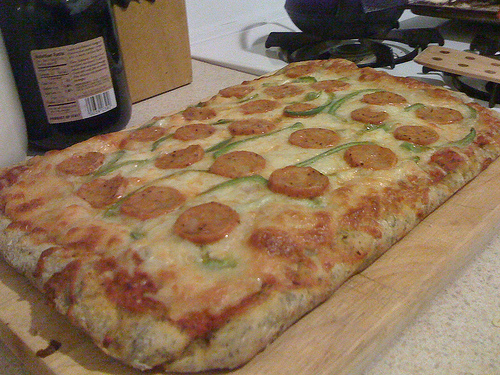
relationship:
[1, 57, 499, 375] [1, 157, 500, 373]
pizza on a board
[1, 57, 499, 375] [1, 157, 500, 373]
pizza on top of a board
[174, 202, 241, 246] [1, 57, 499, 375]
pepperoni on top of pizza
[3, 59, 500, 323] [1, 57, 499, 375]
cheese on top of pizza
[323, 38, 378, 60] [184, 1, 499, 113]
fire on stovetop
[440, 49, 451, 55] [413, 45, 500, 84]
hole in a spatula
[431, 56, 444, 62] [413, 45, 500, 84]
hole in a spatula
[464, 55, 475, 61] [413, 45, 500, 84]
hole in a spatula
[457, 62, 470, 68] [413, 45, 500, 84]
hole in a spatula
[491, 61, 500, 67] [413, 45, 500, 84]
hole in a spatula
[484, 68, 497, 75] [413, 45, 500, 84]
hole in a spatula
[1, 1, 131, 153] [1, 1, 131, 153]
liquid in a bottle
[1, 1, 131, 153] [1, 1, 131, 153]
bottle has liquid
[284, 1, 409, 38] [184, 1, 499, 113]
pan on oven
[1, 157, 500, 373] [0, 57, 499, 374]
board on counter top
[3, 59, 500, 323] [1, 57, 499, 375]
cheese on pizza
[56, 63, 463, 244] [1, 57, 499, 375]
meat on pizza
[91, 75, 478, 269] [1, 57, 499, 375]
green peppers are on pizza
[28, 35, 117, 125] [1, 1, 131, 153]
label on bottle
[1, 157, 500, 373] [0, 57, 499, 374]
board on top of counter top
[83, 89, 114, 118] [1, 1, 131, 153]
bar code on a bottle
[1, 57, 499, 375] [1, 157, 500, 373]
pizza on top of board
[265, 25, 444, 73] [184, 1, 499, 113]
burner on top of a stovetop